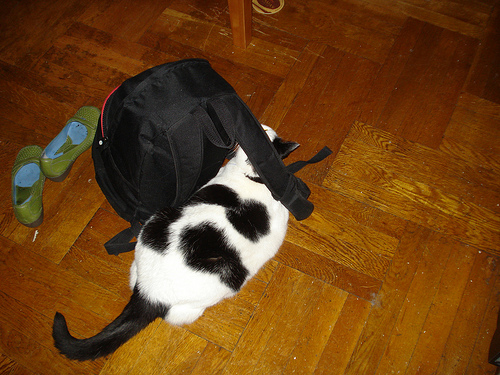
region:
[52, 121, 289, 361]
black and white cat under a back pack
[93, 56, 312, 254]
black back pack on the floor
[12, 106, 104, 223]
green shoes next to a back pack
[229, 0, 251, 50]
leg of a chair on the floor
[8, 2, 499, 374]
hard wood flooring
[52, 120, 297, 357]
white cat with large black spots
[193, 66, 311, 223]
left strap of the back pack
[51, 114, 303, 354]
cat is under a back pack strap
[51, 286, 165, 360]
balck tail of the cat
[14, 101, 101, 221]
green balley flat shoes with blue inside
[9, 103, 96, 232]
a pair of green shoes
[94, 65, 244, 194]
black backpack with red trim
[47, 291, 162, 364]
housecat's tail swishing back-and-forth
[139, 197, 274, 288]
black fur-spots on the cat's white-fur body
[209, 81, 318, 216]
cat's head buried behind backpack strap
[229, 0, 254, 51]
barely visible wooden table leg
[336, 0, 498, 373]
wooden floor with intersecting boards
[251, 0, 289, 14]
copper string on the wooden floor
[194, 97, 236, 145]
hanger for backpack when not in use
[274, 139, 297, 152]
barely visible cat's ear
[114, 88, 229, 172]
a black backpack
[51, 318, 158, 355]
a black tail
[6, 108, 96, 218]
shoes are green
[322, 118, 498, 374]
the wooden floor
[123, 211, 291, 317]
the cat is white and black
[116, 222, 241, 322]
the cat is laying on the floor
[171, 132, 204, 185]
a strap on the backpack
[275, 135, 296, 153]
the cats ear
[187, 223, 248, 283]
spots on the cat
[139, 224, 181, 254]
the cats spots are black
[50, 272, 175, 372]
A black tail on a cat.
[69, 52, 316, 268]
a black cat laying on a hard wood floor.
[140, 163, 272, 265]
a large black spot on a cat.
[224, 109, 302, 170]
the head of a black and white cat.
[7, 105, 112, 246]
a blue and green cat toy.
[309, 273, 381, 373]
a board in a hardwood floor.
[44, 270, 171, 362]
a furry black tail.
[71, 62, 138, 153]
a red collar on a cat.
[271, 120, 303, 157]
a right cat ear.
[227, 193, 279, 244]
a section of a black patch of fur.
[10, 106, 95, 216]
Shoes are on the floor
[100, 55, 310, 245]
bookbag on the floor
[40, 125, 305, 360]
cat laying right next to the bookbag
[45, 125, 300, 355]
The cat is black and white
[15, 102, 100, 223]
Shoes are green on the outside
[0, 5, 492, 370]
The floor is a brown color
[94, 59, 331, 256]
The bookbag on the floor is black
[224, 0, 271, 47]
A chair or table leg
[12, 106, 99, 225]
Shoes are light blue on some of the inside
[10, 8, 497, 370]
The floor is hardwood